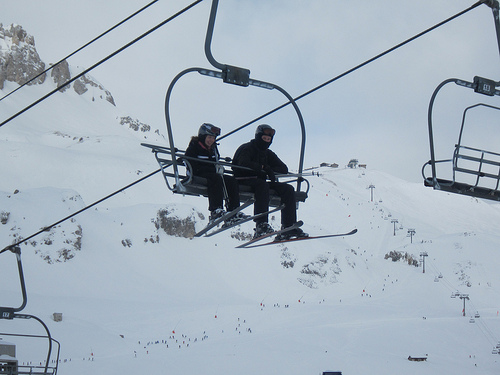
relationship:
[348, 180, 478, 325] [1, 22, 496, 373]
power poles going up a mountain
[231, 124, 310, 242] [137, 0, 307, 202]
man on a ski lift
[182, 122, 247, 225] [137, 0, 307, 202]
person on a ski lift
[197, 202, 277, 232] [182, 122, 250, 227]
skis on a person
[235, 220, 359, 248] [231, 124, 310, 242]
skis on a man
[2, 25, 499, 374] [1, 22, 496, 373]
snow on a mountain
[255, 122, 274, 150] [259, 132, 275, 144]
ski mask over face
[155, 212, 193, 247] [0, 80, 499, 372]
rock showing through snow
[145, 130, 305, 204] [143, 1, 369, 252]
bench on ski lift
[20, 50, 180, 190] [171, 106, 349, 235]
moutain behind skiers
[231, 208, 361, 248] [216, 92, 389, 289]
skis on man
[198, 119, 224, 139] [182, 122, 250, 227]
hat on person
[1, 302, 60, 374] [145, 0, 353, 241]
chair on ski lift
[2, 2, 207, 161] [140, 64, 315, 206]
lines on ski lift